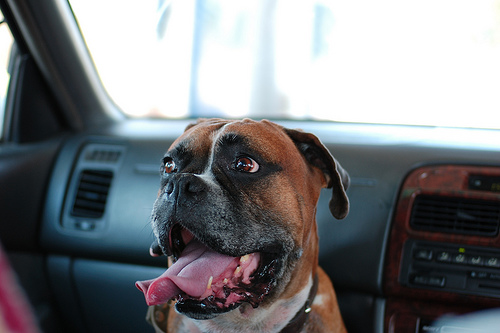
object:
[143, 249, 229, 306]
tongue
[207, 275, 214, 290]
teeth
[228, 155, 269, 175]
eyes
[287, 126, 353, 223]
ear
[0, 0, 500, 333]
car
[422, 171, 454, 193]
wood grain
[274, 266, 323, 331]
collar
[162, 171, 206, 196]
nose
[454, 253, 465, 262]
symbols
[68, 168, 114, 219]
vent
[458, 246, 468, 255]
light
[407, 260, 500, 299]
radio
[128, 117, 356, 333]
dog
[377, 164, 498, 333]
panel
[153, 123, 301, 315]
face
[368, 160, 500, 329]
car's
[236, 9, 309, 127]
windsheild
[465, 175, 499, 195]
dashboard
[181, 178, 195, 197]
nostril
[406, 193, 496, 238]
vent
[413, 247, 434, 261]
climate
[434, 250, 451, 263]
buttons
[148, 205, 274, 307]
mouth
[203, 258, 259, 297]
gums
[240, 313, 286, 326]
white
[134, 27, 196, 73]
light